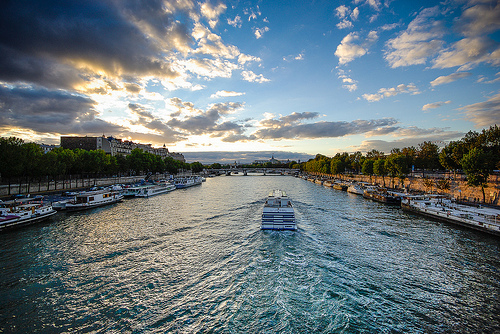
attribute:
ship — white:
[257, 185, 300, 235]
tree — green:
[458, 145, 493, 202]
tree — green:
[372, 156, 391, 185]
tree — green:
[78, 148, 119, 185]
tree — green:
[330, 157, 344, 178]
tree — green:
[125, 147, 155, 175]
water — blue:
[1, 170, 496, 331]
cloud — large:
[2, 1, 217, 99]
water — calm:
[68, 238, 483, 332]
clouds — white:
[347, 12, 432, 71]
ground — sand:
[387, 175, 496, 190]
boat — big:
[259, 195, 294, 237]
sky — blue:
[261, 67, 325, 107]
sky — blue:
[252, 87, 345, 112]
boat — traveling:
[257, 184, 302, 238]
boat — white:
[260, 195, 297, 235]